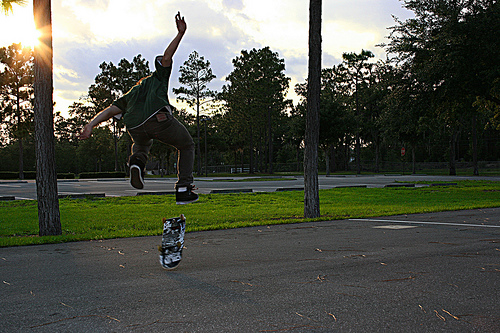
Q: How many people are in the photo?
A: One.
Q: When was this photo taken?
A: During the day.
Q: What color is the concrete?
A: Gray.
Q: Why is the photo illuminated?
A: Sunlight.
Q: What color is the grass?
A: Green.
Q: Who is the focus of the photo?
A: The skateboarder.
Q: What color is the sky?
A: Blue.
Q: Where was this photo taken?
A: On lot.